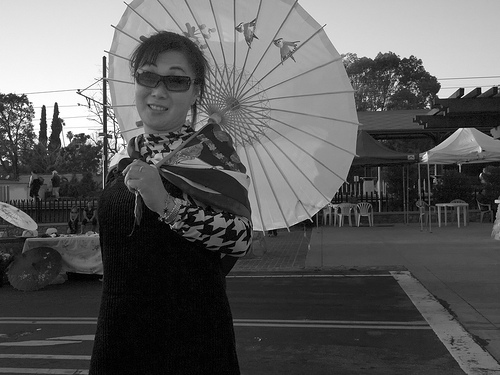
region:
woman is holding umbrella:
[98, 0, 365, 235]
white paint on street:
[1, 266, 463, 373]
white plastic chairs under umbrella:
[310, 197, 499, 232]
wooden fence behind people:
[3, 196, 109, 237]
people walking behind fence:
[18, 166, 63, 203]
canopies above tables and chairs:
[314, 121, 498, 233]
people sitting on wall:
[66, 196, 97, 239]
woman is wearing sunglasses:
[133, 62, 195, 97]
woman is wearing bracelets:
[151, 193, 193, 234]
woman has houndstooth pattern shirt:
[135, 126, 251, 254]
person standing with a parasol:
[74, 8, 344, 373]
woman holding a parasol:
[50, 10, 327, 372]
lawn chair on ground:
[351, 203, 383, 232]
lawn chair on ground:
[340, 201, 355, 226]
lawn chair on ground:
[323, 205, 340, 227]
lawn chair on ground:
[415, 202, 427, 229]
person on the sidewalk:
[80, 205, 95, 230]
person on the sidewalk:
[65, 206, 77, 226]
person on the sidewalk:
[50, 166, 61, 193]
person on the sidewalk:
[27, 170, 47, 205]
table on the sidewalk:
[435, 200, 475, 231]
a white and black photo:
[12, 11, 499, 353]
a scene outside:
[6, 8, 483, 372]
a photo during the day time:
[5, 2, 499, 367]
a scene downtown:
[5, 12, 499, 362]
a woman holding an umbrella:
[65, 6, 370, 363]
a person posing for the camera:
[62, 5, 343, 373]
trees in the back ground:
[2, 32, 497, 204]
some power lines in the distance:
[0, 71, 498, 266]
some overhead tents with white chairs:
[280, 115, 497, 263]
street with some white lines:
[2, 259, 466, 373]